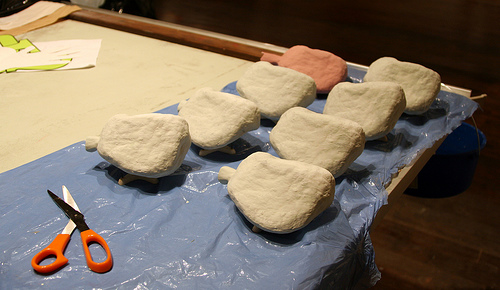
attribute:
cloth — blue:
[20, 80, 327, 278]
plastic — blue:
[0, 58, 477, 288]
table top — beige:
[0, 5, 470, 286]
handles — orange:
[27, 224, 140, 274]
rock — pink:
[251, 38, 362, 93]